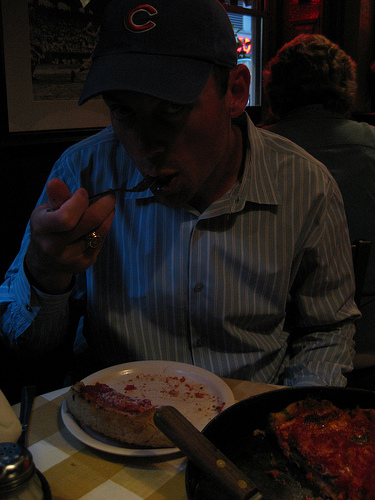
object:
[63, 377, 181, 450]
pizza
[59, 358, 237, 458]
plate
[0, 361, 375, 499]
table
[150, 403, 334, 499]
knife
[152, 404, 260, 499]
handle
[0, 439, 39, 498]
dispenser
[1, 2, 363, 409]
man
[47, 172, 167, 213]
fork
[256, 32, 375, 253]
woman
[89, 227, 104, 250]
ring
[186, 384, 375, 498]
platter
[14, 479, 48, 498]
cheese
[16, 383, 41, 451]
silverware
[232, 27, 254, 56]
sign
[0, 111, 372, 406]
blouse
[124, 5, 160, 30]
chicago symbol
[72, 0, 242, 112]
cap